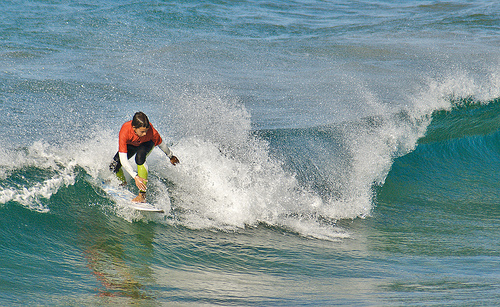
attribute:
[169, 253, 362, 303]
water — smooth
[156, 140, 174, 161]
sleeve — white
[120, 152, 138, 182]
sleeve — white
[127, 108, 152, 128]
hair — wet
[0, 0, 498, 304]
ocean — big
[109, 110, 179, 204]
person — wet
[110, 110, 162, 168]
dress — orange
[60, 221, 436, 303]
ocean — green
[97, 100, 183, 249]
person — surfing 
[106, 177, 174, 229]
board — white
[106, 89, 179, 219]
person — surfing 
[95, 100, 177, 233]
person — surfing 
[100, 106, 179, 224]
person — surfing 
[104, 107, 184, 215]
person — surfing 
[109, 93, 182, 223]
person — surfing 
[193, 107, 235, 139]
droplet — water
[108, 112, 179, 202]
boy — surfing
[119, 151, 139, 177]
sleeve — white, long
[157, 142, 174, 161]
sleeve — white, long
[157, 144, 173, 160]
sleeve — long, white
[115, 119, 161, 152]
shirt — red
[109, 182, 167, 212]
surfboard — white